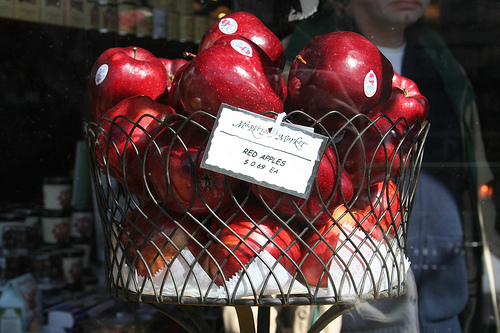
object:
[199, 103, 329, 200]
tag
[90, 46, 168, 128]
apples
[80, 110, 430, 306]
basket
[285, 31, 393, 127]
apple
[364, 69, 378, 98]
sticker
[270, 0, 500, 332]
man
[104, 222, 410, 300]
lining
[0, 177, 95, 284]
items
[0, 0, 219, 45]
items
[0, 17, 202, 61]
shelf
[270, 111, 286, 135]
strap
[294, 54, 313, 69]
stem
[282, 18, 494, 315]
jacket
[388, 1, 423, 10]
mouth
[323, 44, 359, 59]
part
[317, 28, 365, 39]
edge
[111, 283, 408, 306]
bottom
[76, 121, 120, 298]
side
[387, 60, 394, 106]
side